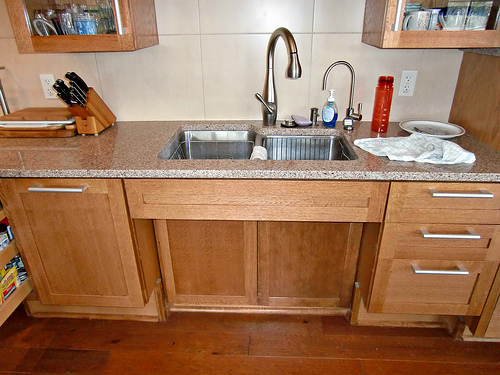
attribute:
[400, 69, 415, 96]
outlet — white, electrical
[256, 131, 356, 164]
sink — metal, empty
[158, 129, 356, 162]
sink — silver, metal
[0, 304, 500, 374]
floor — dark, wooden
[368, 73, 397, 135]
water bottle — orange, plastic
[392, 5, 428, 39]
mug — white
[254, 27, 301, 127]
faucet — stainless steel, water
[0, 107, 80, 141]
boards — cutting, stacked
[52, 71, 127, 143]
knife block — wooden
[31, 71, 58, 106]
outlet — wall, white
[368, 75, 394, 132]
bottle — drinking, red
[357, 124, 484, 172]
towel — white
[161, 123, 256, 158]
sink — stainless steel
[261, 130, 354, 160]
sink — stainless steel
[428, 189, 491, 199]
handle — metal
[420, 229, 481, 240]
handle — metal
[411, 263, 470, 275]
handle — metal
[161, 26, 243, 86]
tile — white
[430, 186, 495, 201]
handle — stainless steel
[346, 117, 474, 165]
towel — white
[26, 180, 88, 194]
handle — metal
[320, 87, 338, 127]
bottle — plastic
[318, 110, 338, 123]
hand soap — blue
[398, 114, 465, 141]
plate — white, dinner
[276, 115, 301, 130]
sink stopper — metal